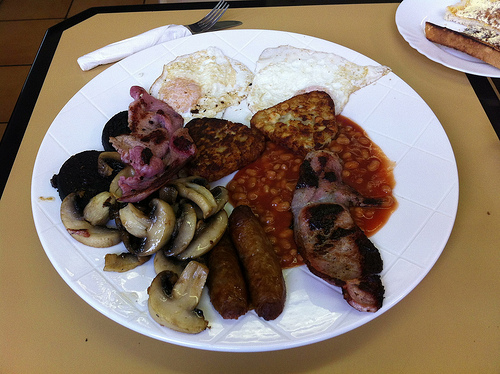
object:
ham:
[290, 150, 392, 313]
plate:
[30, 28, 460, 352]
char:
[354, 235, 385, 310]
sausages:
[205, 204, 287, 320]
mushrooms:
[59, 176, 228, 335]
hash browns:
[183, 90, 339, 184]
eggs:
[149, 44, 390, 118]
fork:
[76, 0, 229, 74]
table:
[0, 0, 500, 374]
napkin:
[77, 24, 192, 72]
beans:
[226, 123, 396, 267]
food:
[49, 44, 393, 337]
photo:
[0, 0, 500, 374]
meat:
[205, 150, 394, 320]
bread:
[424, 0, 500, 70]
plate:
[394, 0, 500, 78]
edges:
[0, 6, 93, 154]